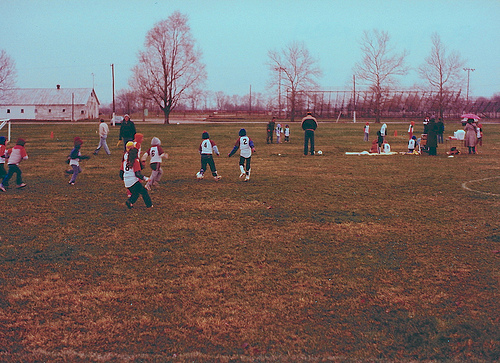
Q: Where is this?
A: This is at the field.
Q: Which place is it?
A: It is a field.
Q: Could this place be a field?
A: Yes, it is a field.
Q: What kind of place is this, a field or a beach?
A: It is a field.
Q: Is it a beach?
A: No, it is a field.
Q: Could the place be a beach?
A: No, it is a field.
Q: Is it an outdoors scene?
A: Yes, it is outdoors.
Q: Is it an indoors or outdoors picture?
A: It is outdoors.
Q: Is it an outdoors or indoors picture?
A: It is outdoors.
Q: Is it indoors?
A: No, it is outdoors.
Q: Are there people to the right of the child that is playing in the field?
A: Yes, there is a person to the right of the kid.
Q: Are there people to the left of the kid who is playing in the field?
A: No, the person is to the right of the kid.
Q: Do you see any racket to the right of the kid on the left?
A: No, there is a person to the right of the child.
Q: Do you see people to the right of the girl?
A: Yes, there is a person to the right of the girl.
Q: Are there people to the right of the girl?
A: Yes, there is a person to the right of the girl.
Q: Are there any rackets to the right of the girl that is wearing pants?
A: No, there is a person to the right of the girl.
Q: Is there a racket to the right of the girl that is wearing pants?
A: No, there is a person to the right of the girl.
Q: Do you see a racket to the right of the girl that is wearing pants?
A: No, there is a person to the right of the girl.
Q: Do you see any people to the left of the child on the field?
A: Yes, there is a person to the left of the child.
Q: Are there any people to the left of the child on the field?
A: Yes, there is a person to the left of the child.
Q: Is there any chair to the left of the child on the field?
A: No, there is a person to the left of the kid.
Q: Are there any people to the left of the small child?
A: Yes, there is a person to the left of the kid.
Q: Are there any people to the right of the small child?
A: No, the person is to the left of the child.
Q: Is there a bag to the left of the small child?
A: No, there is a person to the left of the kid.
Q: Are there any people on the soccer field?
A: Yes, there is a person on the field.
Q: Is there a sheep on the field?
A: No, there is a person on the field.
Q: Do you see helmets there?
A: No, there are no helmets.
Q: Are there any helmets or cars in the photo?
A: No, there are no helmets or cars.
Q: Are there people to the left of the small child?
A: Yes, there is a person to the left of the child.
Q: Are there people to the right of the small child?
A: No, the person is to the left of the kid.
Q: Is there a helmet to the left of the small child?
A: No, there is a person to the left of the kid.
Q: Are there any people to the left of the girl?
A: Yes, there is a person to the left of the girl.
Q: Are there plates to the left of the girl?
A: No, there is a person to the left of the girl.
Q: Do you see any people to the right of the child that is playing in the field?
A: Yes, there is a person to the right of the child.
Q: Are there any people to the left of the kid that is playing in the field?
A: No, the person is to the right of the kid.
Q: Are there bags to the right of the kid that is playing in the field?
A: No, there is a person to the right of the kid.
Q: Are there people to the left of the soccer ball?
A: Yes, there is a person to the left of the soccer ball.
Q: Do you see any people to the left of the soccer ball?
A: Yes, there is a person to the left of the soccer ball.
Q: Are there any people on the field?
A: Yes, there is a person on the field.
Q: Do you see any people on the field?
A: Yes, there is a person on the field.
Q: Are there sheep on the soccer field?
A: No, there is a person on the field.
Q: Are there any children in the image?
A: Yes, there is a child.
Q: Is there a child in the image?
A: Yes, there is a child.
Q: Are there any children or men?
A: Yes, there is a child.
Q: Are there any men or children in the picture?
A: Yes, there is a child.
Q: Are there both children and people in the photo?
A: Yes, there are both a child and a person.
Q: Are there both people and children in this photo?
A: Yes, there are both a child and a person.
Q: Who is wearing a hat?
A: The child is wearing a hat.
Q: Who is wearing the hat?
A: The child is wearing a hat.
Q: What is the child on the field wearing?
A: The kid is wearing a hat.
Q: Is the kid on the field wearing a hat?
A: Yes, the kid is wearing a hat.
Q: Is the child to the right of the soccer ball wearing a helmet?
A: No, the kid is wearing a hat.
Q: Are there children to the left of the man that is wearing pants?
A: Yes, there is a child to the left of the man.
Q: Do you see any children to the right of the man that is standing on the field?
A: No, the child is to the left of the man.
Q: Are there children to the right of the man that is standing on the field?
A: No, the child is to the left of the man.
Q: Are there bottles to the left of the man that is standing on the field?
A: No, there is a child to the left of the man.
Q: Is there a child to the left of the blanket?
A: Yes, there is a child to the left of the blanket.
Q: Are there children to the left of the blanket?
A: Yes, there is a child to the left of the blanket.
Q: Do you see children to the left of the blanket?
A: Yes, there is a child to the left of the blanket.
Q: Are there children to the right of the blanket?
A: No, the child is to the left of the blanket.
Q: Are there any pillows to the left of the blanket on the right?
A: No, there is a child to the left of the blanket.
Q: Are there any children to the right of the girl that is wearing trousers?
A: Yes, there is a child to the right of the girl.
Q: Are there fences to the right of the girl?
A: No, there is a child to the right of the girl.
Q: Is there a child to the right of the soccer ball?
A: Yes, there is a child to the right of the soccer ball.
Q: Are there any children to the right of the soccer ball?
A: Yes, there is a child to the right of the soccer ball.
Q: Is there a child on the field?
A: Yes, there is a child on the field.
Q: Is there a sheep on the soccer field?
A: No, there is a child on the field.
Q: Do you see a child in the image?
A: Yes, there is a child.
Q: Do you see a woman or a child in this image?
A: Yes, there is a child.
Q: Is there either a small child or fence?
A: Yes, there is a small child.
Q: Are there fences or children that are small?
A: Yes, the child is small.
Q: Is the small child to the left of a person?
A: No, the child is to the right of a person.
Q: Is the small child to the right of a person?
A: Yes, the child is to the right of a person.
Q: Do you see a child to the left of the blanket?
A: Yes, there is a child to the left of the blanket.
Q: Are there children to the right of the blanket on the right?
A: No, the child is to the left of the blanket.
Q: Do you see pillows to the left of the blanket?
A: No, there is a child to the left of the blanket.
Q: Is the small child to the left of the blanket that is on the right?
A: Yes, the kid is to the left of the blanket.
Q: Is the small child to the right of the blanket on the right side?
A: No, the kid is to the left of the blanket.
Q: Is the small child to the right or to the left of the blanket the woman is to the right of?
A: The kid is to the left of the blanket.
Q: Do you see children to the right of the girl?
A: Yes, there is a child to the right of the girl.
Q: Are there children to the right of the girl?
A: Yes, there is a child to the right of the girl.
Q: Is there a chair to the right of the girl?
A: No, there is a child to the right of the girl.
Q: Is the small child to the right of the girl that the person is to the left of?
A: Yes, the kid is to the right of the girl.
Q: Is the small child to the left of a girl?
A: No, the child is to the right of a girl.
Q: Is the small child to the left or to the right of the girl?
A: The child is to the right of the girl.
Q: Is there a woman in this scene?
A: Yes, there is a woman.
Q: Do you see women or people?
A: Yes, there is a woman.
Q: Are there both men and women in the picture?
A: Yes, there are both a woman and a man.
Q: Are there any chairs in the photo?
A: No, there are no chairs.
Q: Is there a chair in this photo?
A: No, there are no chairs.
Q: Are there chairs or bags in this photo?
A: No, there are no chairs or bags.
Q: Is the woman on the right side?
A: Yes, the woman is on the right of the image.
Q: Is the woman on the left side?
A: No, the woman is on the right of the image.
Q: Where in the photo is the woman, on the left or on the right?
A: The woman is on the right of the image.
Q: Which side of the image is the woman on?
A: The woman is on the right of the image.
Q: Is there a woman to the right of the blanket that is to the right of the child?
A: Yes, there is a woman to the right of the blanket.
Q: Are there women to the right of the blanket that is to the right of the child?
A: Yes, there is a woman to the right of the blanket.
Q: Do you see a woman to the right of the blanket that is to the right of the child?
A: Yes, there is a woman to the right of the blanket.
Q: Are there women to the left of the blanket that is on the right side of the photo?
A: No, the woman is to the right of the blanket.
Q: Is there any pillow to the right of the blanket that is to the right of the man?
A: No, there is a woman to the right of the blanket.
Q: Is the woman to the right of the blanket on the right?
A: Yes, the woman is to the right of the blanket.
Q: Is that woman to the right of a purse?
A: No, the woman is to the right of the blanket.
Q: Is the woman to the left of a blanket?
A: No, the woman is to the right of a blanket.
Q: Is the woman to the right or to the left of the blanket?
A: The woman is to the right of the blanket.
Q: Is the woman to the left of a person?
A: No, the woman is to the right of a person.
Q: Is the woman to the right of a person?
A: Yes, the woman is to the right of a person.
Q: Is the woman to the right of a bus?
A: No, the woman is to the right of a person.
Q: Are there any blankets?
A: Yes, there is a blanket.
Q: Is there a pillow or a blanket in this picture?
A: Yes, there is a blanket.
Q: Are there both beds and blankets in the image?
A: No, there is a blanket but no beds.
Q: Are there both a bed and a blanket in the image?
A: No, there is a blanket but no beds.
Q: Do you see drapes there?
A: No, there are no drapes.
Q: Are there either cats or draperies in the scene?
A: No, there are no draperies or cats.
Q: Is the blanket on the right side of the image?
A: Yes, the blanket is on the right of the image.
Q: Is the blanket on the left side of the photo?
A: No, the blanket is on the right of the image.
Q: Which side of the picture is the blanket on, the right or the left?
A: The blanket is on the right of the image.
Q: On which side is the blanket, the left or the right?
A: The blanket is on the right of the image.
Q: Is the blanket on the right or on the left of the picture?
A: The blanket is on the right of the image.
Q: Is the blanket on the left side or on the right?
A: The blanket is on the right of the image.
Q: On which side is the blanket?
A: The blanket is on the right of the image.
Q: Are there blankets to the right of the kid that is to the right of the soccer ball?
A: Yes, there is a blanket to the right of the kid.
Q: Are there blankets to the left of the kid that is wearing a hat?
A: No, the blanket is to the right of the child.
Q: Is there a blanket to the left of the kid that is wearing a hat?
A: No, the blanket is to the right of the child.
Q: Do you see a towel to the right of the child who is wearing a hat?
A: No, there is a blanket to the right of the child.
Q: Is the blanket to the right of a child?
A: Yes, the blanket is to the right of a child.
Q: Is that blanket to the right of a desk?
A: No, the blanket is to the right of a child.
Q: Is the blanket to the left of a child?
A: No, the blanket is to the right of a child.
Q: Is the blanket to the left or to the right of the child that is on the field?
A: The blanket is to the right of the child.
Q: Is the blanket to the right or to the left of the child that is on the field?
A: The blanket is to the right of the child.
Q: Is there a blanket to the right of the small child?
A: Yes, there is a blanket to the right of the kid.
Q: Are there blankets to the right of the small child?
A: Yes, there is a blanket to the right of the kid.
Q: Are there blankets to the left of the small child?
A: No, the blanket is to the right of the kid.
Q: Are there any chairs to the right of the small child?
A: No, there is a blanket to the right of the kid.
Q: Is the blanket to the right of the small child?
A: Yes, the blanket is to the right of the kid.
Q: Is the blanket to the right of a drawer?
A: No, the blanket is to the right of the kid.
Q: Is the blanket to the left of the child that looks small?
A: No, the blanket is to the right of the child.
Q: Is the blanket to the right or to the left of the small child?
A: The blanket is to the right of the child.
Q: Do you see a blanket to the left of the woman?
A: Yes, there is a blanket to the left of the woman.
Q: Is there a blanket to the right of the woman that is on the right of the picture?
A: No, the blanket is to the left of the woman.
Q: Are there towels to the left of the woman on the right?
A: No, there is a blanket to the left of the woman.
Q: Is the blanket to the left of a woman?
A: Yes, the blanket is to the left of a woman.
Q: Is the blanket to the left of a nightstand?
A: No, the blanket is to the left of a woman.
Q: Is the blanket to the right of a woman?
A: No, the blanket is to the left of a woman.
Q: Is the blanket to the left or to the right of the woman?
A: The blanket is to the left of the woman.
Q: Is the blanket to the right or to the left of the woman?
A: The blanket is to the left of the woman.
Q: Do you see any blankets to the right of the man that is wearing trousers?
A: Yes, there is a blanket to the right of the man.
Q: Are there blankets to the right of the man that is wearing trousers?
A: Yes, there is a blanket to the right of the man.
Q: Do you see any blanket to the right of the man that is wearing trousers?
A: Yes, there is a blanket to the right of the man.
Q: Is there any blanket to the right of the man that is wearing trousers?
A: Yes, there is a blanket to the right of the man.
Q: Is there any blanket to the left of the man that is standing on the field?
A: No, the blanket is to the right of the man.